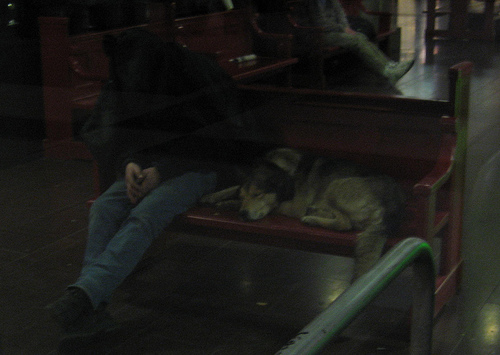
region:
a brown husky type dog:
[203, 122, 418, 256]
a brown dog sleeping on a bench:
[210, 143, 425, 291]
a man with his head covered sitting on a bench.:
[48, 20, 265, 328]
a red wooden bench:
[68, 64, 489, 345]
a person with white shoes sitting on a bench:
[298, 3, 425, 92]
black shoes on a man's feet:
[52, 271, 136, 353]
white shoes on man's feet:
[383, 60, 423, 90]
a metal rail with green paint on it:
[243, 193, 432, 350]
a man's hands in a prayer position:
[124, 157, 168, 209]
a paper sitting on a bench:
[223, 45, 263, 70]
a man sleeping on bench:
[38, 31, 203, 351]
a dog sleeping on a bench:
[240, 145, 386, 260]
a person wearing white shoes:
[314, 5, 423, 96]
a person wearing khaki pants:
[316, 0, 431, 101]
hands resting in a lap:
[125, 162, 157, 192]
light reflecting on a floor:
[471, 297, 498, 348]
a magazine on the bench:
[226, 46, 266, 67]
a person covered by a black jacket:
[94, 51, 235, 190]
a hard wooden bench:
[104, 85, 498, 270]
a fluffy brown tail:
[351, 237, 379, 283]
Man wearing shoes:
[46, 285, 116, 329]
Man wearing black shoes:
[41, 277, 112, 331]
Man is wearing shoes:
[40, 275, 112, 329]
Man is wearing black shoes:
[40, 280, 110, 329]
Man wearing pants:
[72, 161, 219, 310]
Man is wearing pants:
[61, 169, 223, 311]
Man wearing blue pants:
[57, 161, 215, 311]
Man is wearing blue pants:
[58, 162, 218, 317]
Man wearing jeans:
[70, 161, 214, 319]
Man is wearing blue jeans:
[65, 157, 219, 314]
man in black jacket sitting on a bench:
[48, 33, 246, 340]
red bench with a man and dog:
[93, 65, 468, 320]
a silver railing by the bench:
[237, 240, 434, 353]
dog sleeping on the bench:
[204, 151, 406, 283]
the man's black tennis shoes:
[46, 290, 123, 346]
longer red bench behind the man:
[33, 9, 378, 154]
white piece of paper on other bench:
[226, 51, 255, 63]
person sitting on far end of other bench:
[305, 2, 413, 81]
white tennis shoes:
[383, 55, 416, 90]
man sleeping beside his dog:
[51, 45, 400, 344]